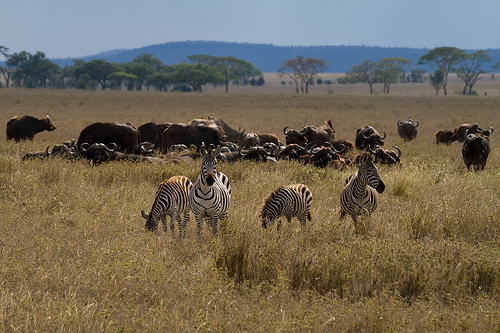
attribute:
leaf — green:
[158, 70, 161, 72]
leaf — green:
[192, 67, 193, 69]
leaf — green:
[103, 71, 107, 74]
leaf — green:
[119, 71, 124, 76]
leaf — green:
[151, 64, 153, 66]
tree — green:
[108, 60, 158, 88]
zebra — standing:
[341, 157, 400, 211]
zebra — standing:
[263, 173, 325, 226]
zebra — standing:
[191, 149, 254, 213]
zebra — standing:
[139, 156, 199, 220]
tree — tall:
[420, 37, 462, 100]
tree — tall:
[461, 40, 491, 95]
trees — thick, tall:
[73, 50, 140, 102]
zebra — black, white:
[191, 143, 231, 241]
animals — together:
[53, 71, 497, 295]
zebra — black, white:
[187, 151, 232, 238]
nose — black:
[192, 167, 222, 195]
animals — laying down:
[49, 113, 151, 160]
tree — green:
[278, 55, 328, 95]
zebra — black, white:
[139, 173, 192, 235]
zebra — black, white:
[256, 182, 312, 230]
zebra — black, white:
[335, 152, 385, 229]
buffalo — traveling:
[4, 110, 59, 142]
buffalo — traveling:
[80, 119, 139, 151]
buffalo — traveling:
[158, 122, 220, 154]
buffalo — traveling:
[137, 122, 174, 144]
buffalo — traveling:
[78, 141, 156, 167]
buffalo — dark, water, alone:
[7, 110, 74, 147]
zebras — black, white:
[123, 142, 406, 253]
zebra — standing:
[160, 144, 284, 223]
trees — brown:
[277, 55, 331, 97]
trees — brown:
[15, 44, 258, 95]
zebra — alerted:
[188, 144, 237, 234]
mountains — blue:
[8, 39, 499, 79]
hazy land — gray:
[3, 38, 498, 73]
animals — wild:
[340, 149, 387, 230]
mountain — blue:
[181, 16, 455, 100]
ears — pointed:
[197, 143, 221, 156]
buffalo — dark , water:
[77, 111, 397, 168]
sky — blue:
[2, 2, 498, 53]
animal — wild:
[341, 156, 386, 227]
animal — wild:
[262, 181, 312, 231]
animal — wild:
[188, 141, 230, 233]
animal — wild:
[144, 174, 191, 234]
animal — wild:
[398, 113, 423, 143]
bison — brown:
[3, 114, 55, 148]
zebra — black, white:
[259, 185, 312, 223]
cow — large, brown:
[4, 110, 59, 154]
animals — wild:
[139, 153, 387, 242]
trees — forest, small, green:
[13, 33, 484, 98]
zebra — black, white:
[336, 151, 384, 221]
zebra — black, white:
[135, 172, 195, 230]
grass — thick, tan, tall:
[11, 243, 496, 320]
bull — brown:
[353, 123, 387, 148]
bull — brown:
[302, 117, 336, 143]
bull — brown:
[75, 118, 140, 150]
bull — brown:
[162, 118, 214, 143]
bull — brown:
[134, 118, 174, 143]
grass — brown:
[249, 244, 386, 323]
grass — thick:
[0, 84, 500, 331]